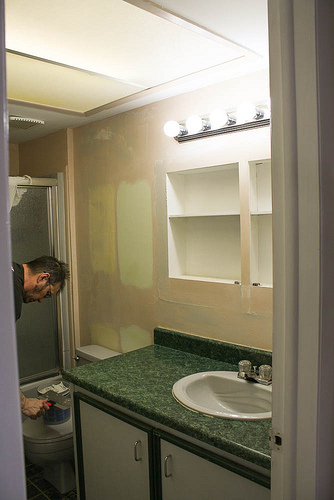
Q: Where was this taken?
A: Bathroom.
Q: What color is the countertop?
A: Green.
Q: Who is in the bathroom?
A: A man.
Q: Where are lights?
A: On the wall.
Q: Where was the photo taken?
A: In a bathroom.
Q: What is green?
A: Countertop.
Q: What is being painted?
A: The wall.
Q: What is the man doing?
A: Painting.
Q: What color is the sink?
A: White.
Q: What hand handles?
A: Cabinets.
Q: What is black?
A: Man's shirt.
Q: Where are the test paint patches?
A: Above the toilet tank.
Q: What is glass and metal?
A: A shower door.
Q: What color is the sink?
A: White.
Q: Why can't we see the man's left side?
A: The photographer is facing the man's right.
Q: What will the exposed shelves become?
A: A medicine cabinet.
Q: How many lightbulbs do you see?
A: 1.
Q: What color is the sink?
A: White.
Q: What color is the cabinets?
A: White and green.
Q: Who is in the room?
A: A man.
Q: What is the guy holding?
A: A paint roller.